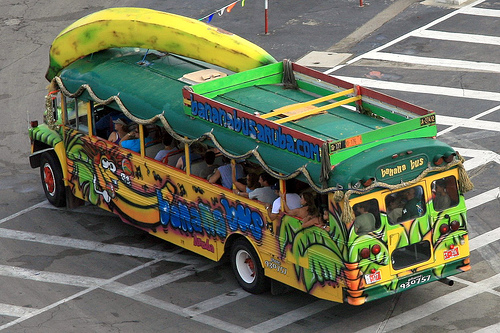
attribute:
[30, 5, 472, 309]
bus — yellow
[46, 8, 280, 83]
banana — yellow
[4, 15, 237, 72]
banana — yellow, green, large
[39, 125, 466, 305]
paint — decorative